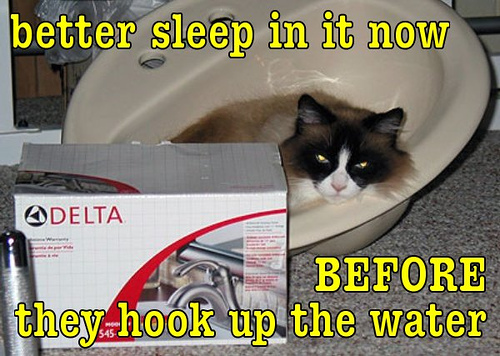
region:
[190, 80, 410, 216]
cat has brown fur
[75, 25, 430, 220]
sink on grey floor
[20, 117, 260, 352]
red and white box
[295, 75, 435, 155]
cat has dark ears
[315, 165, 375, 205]
white streak on face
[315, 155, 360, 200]
cat has light nose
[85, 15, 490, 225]
tan sink on floor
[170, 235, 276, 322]
metal faucet on box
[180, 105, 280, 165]
cat has light brown fur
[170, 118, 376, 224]
cat lying in sink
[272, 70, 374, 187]
this is a cat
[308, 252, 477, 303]
this is a writing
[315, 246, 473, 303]
the writing is in yellow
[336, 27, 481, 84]
this is a sink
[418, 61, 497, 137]
the sink is white in color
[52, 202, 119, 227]
the writing is in red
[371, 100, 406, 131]
this is the ear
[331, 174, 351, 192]
this is the nose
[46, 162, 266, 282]
this is a box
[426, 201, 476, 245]
this is the floor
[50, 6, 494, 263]
cat laying in the sink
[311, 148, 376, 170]
two small eyes on the face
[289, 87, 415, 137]
two small pointy ears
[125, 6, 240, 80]
two holes in the top of the sink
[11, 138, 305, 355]
box sitting on the countertop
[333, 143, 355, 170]
white stripe between the eyes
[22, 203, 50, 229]
black and white logo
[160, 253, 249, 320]
picture of a silver faucet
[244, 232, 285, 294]
small red writing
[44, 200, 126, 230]
red writing in all caps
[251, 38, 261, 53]
part of a letter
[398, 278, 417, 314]
part of a floor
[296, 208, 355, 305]
edge of a sink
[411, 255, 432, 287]
part of a floor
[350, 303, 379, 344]
part of a floor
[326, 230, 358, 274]
part of a sinkl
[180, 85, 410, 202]
a cat laying in a sink basin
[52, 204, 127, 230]
red lettering on a white box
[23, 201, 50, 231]
black logo on a white box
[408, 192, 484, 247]
grey carpet of the ground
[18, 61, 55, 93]
brown wood surface of a cabinet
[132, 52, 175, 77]
hole in the sink basin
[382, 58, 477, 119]
white porcelain surface of the sink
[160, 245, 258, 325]
picture of a faucet on the box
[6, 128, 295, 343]
a white cardboard box on the ground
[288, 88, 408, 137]
black pointed ears of the cat